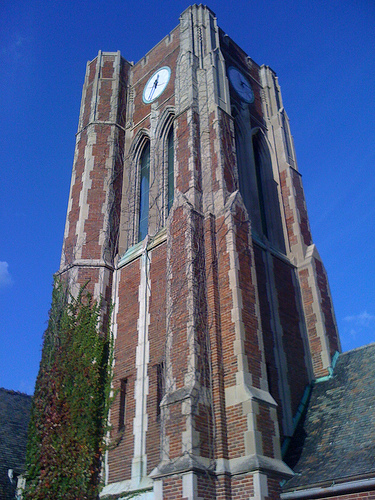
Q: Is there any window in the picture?
A: Yes, there is a window.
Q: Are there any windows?
A: Yes, there is a window.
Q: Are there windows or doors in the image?
A: Yes, there is a window.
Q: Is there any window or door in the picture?
A: Yes, there is a window.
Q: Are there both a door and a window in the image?
A: No, there is a window but no doors.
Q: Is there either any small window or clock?
A: Yes, there is a small window.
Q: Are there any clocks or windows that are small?
A: Yes, the window is small.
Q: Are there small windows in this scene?
A: Yes, there is a small window.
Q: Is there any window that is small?
A: Yes, there is a window that is small.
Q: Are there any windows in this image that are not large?
A: Yes, there is a small window.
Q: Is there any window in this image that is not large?
A: Yes, there is a small window.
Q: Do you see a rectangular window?
A: Yes, there is a rectangular window.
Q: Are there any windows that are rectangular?
A: Yes, there is a window that is rectangular.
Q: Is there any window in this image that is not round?
A: Yes, there is a rectangular window.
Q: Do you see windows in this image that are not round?
A: Yes, there is a rectangular window.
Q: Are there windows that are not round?
A: Yes, there is a rectangular window.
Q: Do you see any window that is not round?
A: Yes, there is a rectangular window.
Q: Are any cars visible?
A: No, there are no cars.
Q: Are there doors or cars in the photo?
A: No, there are no cars or doors.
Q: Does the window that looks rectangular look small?
A: Yes, the window is small.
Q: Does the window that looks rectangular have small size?
A: Yes, the window is small.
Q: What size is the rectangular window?
A: The window is small.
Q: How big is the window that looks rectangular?
A: The window is small.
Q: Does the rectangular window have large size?
A: No, the window is small.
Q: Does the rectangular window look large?
A: No, the window is small.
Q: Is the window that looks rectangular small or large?
A: The window is small.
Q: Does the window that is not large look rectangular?
A: Yes, the window is rectangular.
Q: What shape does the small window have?
A: The window has rectangular shape.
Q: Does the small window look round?
A: No, the window is rectangular.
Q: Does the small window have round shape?
A: No, the window is rectangular.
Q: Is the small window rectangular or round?
A: The window is rectangular.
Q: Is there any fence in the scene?
A: No, there are no fences.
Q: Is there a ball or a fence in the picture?
A: No, there are no fences or balls.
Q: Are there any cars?
A: No, there are no cars.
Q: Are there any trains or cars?
A: No, there are no cars or trains.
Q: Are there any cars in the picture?
A: No, there are no cars.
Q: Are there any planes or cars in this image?
A: No, there are no cars or planes.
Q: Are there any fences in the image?
A: No, there are no fences.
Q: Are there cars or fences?
A: No, there are no fences or cars.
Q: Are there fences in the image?
A: No, there are no fences.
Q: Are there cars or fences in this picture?
A: No, there are no fences or cars.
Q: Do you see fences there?
A: No, there are no fences.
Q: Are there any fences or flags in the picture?
A: No, there are no fences or flags.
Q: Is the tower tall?
A: Yes, the tower is tall.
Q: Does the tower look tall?
A: Yes, the tower is tall.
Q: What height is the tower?
A: The tower is tall.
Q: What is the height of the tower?
A: The tower is tall.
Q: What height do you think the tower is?
A: The tower is tall.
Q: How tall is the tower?
A: The tower is tall.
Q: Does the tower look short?
A: No, the tower is tall.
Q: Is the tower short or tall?
A: The tower is tall.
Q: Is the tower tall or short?
A: The tower is tall.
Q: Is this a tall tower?
A: Yes, this is a tall tower.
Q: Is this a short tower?
A: No, this is a tall tower.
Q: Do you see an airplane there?
A: No, there are no airplanes.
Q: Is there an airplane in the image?
A: No, there are no airplanes.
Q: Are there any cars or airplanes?
A: No, there are no airplanes or cars.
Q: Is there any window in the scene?
A: Yes, there is a window.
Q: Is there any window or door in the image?
A: Yes, there is a window.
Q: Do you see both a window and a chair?
A: No, there is a window but no chairs.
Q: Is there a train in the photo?
A: No, there are no trains.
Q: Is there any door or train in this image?
A: No, there are no trains or doors.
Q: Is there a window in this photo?
A: Yes, there is a window.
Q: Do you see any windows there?
A: Yes, there is a window.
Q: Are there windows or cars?
A: Yes, there is a window.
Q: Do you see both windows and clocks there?
A: Yes, there are both a window and a clock.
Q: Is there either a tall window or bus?
A: Yes, there is a tall window.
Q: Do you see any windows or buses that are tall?
A: Yes, the window is tall.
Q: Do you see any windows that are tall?
A: Yes, there is a tall window.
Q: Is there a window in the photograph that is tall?
A: Yes, there is a window that is tall.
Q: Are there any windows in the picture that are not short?
A: Yes, there is a tall window.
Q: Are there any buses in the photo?
A: No, there are no buses.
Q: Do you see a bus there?
A: No, there are no buses.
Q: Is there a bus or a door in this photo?
A: No, there are no buses or doors.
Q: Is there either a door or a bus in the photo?
A: No, there are no buses or doors.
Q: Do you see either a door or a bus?
A: No, there are no buses or doors.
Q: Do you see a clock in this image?
A: Yes, there is a clock.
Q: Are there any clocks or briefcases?
A: Yes, there is a clock.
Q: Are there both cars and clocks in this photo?
A: No, there is a clock but no cars.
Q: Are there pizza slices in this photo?
A: No, there are no pizza slices.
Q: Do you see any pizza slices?
A: No, there are no pizza slices.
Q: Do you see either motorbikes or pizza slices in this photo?
A: No, there are no pizza slices or motorbikes.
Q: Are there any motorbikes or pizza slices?
A: No, there are no pizza slices or motorbikes.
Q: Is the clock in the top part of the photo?
A: Yes, the clock is in the top of the image.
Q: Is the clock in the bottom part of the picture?
A: No, the clock is in the top of the image.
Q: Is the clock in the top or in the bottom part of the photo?
A: The clock is in the top of the image.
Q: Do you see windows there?
A: Yes, there is a window.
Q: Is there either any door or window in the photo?
A: Yes, there is a window.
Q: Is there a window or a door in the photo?
A: Yes, there is a window.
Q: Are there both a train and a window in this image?
A: No, there is a window but no trains.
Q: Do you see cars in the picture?
A: No, there are no cars.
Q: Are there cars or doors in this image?
A: No, there are no cars or doors.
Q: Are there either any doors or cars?
A: No, there are no cars or doors.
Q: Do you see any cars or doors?
A: No, there are no cars or doors.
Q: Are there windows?
A: Yes, there is a window.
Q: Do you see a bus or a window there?
A: Yes, there is a window.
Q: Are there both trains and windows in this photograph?
A: No, there is a window but no trains.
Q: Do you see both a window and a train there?
A: No, there is a window but no trains.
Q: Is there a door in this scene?
A: No, there are no doors.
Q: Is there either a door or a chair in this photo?
A: No, there are no doors or chairs.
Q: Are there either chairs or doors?
A: No, there are no doors or chairs.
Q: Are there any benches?
A: No, there are no benches.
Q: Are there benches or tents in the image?
A: No, there are no benches or tents.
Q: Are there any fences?
A: No, there are no fences.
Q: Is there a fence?
A: No, there are no fences.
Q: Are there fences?
A: No, there are no fences.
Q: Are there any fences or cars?
A: No, there are no fences or cars.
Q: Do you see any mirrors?
A: No, there are no mirrors.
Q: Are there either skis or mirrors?
A: No, there are no mirrors or skis.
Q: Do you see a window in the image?
A: Yes, there is a window.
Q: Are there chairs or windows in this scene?
A: Yes, there is a window.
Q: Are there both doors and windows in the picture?
A: No, there is a window but no doors.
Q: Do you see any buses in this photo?
A: No, there are no buses.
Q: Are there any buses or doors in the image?
A: No, there are no buses or doors.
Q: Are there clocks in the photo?
A: Yes, there is a clock.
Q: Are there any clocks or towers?
A: Yes, there is a clock.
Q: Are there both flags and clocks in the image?
A: No, there is a clock but no flags.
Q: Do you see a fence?
A: No, there are no fences.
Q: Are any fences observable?
A: No, there are no fences.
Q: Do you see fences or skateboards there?
A: No, there are no fences or skateboards.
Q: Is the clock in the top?
A: Yes, the clock is in the top of the image.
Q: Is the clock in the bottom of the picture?
A: No, the clock is in the top of the image.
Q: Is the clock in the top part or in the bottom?
A: The clock is in the top of the image.